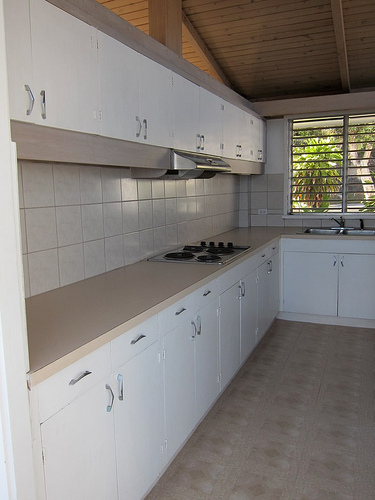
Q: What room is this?
A: Kitchen.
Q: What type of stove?
A: Electric.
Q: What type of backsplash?
A: Tile.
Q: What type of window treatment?
A: Blinds.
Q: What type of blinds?
A: Wood.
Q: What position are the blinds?
A: Open.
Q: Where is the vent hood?
A: Above the stove.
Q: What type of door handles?
A: Silver.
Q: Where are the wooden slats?
A: The ceiling.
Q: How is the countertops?
A: Beige.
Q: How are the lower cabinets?
A: White.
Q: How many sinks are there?
A: 1.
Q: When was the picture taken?
A: In the daytime.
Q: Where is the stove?
A: On the left.